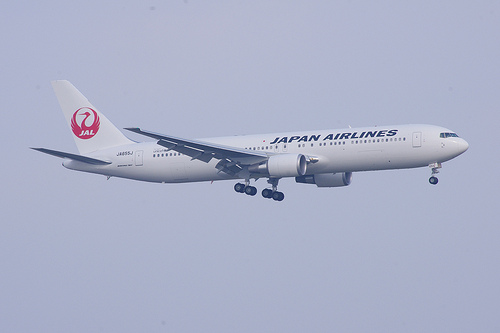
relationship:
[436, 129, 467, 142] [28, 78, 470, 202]
windows on front of airplane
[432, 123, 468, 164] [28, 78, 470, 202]
cockpit on airplane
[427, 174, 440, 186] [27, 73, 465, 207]
front wheels on airplane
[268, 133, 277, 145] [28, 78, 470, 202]
lettering on airplane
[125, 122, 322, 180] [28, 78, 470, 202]
wing on airplane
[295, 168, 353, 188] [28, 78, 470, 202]
jet engines on airplane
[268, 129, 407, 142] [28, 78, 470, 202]
words on a airplane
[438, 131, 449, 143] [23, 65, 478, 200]
window on front of a plane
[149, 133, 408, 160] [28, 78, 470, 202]
window line on side of airplane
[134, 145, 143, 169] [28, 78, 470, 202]
door on back of airplane